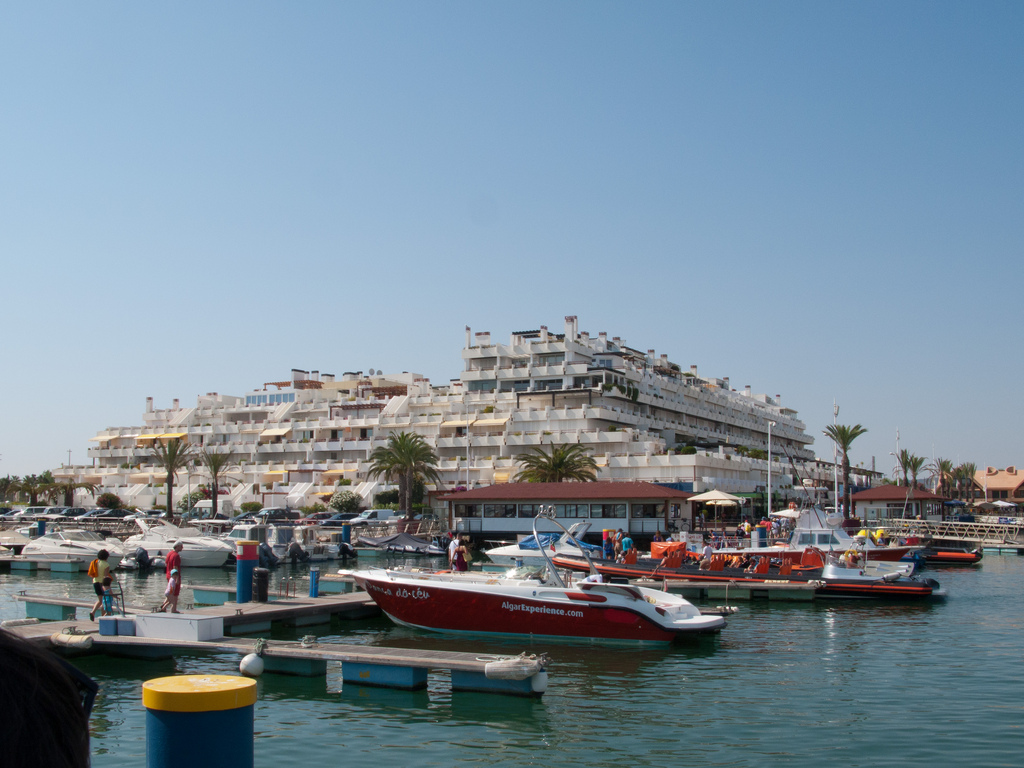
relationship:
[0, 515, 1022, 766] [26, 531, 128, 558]
marina on boat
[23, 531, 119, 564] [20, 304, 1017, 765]
boat on pier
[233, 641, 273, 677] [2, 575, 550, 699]
buoy on dock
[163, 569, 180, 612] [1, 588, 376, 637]
person on dock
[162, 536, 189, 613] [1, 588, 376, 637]
man on dock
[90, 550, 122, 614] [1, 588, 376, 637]
person on dock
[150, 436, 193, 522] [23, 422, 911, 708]
palm tree on pier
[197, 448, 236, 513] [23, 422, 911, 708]
palm tree on pier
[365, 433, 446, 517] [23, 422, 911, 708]
palm tree on pier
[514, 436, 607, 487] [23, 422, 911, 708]
palm tree on pier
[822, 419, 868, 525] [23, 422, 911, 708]
palm tree on pier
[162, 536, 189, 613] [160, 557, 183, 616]
man with child